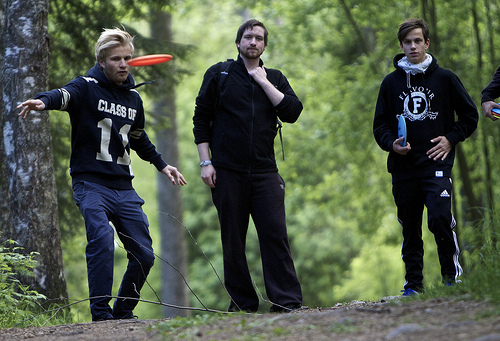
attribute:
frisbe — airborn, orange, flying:
[123, 44, 176, 73]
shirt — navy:
[89, 92, 135, 177]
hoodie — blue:
[382, 64, 476, 143]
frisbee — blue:
[385, 115, 417, 146]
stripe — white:
[448, 195, 464, 276]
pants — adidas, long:
[376, 183, 466, 288]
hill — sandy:
[184, 279, 459, 341]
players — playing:
[42, 29, 462, 263]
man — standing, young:
[213, 15, 287, 310]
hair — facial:
[245, 50, 264, 63]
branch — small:
[70, 293, 283, 321]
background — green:
[41, 18, 489, 166]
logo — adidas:
[218, 65, 234, 75]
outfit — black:
[201, 83, 300, 255]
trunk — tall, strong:
[14, 75, 61, 294]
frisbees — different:
[482, 97, 499, 128]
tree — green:
[289, 14, 368, 186]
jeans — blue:
[78, 186, 154, 304]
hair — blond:
[92, 19, 119, 53]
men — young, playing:
[37, 35, 480, 173]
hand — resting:
[421, 132, 454, 164]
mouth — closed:
[246, 46, 262, 53]